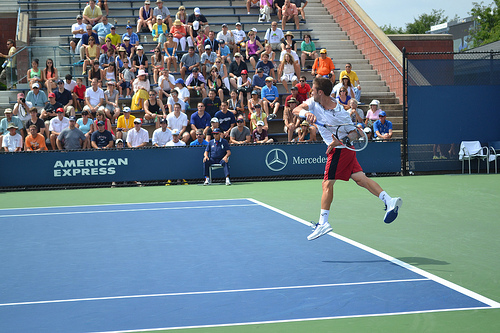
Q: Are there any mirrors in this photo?
A: No, there are no mirrors.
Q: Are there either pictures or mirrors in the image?
A: No, there are no mirrors or pictures.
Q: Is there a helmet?
A: No, there are no helmets.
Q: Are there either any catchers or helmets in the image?
A: No, there are no helmets or catchers.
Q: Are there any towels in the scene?
A: Yes, there is a towel.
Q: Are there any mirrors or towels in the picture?
A: Yes, there is a towel.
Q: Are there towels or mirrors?
A: Yes, there is a towel.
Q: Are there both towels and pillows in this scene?
A: No, there is a towel but no pillows.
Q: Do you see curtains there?
A: No, there are no curtains.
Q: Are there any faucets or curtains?
A: No, there are no curtains or faucets.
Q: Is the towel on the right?
A: Yes, the towel is on the right of the image.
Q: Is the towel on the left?
A: No, the towel is on the right of the image.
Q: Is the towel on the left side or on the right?
A: The towel is on the right of the image.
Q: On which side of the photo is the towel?
A: The towel is on the right of the image.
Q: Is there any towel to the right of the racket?
A: Yes, there is a towel to the right of the racket.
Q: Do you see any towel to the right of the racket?
A: Yes, there is a towel to the right of the racket.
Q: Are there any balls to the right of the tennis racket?
A: No, there is a towel to the right of the tennis racket.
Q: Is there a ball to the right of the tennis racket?
A: No, there is a towel to the right of the tennis racket.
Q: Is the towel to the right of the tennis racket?
A: Yes, the towel is to the right of the tennis racket.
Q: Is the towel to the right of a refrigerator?
A: No, the towel is to the right of the tennis racket.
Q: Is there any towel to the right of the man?
A: Yes, there is a towel to the right of the man.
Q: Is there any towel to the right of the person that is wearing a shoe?
A: Yes, there is a towel to the right of the man.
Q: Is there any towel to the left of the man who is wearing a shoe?
A: No, the towel is to the right of the man.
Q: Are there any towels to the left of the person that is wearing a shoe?
A: No, the towel is to the right of the man.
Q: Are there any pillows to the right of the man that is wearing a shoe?
A: No, there is a towel to the right of the man.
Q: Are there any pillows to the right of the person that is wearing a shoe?
A: No, there is a towel to the right of the man.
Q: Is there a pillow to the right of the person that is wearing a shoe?
A: No, there is a towel to the right of the man.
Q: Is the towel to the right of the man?
A: Yes, the towel is to the right of the man.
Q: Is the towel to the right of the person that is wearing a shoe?
A: Yes, the towel is to the right of the man.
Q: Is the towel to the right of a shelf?
A: No, the towel is to the right of the man.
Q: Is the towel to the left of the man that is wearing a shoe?
A: No, the towel is to the right of the man.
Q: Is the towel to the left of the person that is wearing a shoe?
A: No, the towel is to the right of the man.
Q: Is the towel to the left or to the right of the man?
A: The towel is to the right of the man.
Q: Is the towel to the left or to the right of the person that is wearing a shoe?
A: The towel is to the right of the man.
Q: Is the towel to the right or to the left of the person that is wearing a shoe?
A: The towel is to the right of the man.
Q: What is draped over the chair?
A: The towel is draped over the chair.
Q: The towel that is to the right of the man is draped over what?
A: The towel is draped over the chair.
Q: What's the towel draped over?
A: The towel is draped over the chair.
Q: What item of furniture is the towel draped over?
A: The towel is draped over the chair.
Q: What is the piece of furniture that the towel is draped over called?
A: The piece of furniture is a chair.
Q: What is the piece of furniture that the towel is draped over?
A: The piece of furniture is a chair.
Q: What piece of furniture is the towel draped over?
A: The towel is draped over the chair.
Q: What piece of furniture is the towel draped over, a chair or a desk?
A: The towel is draped over a chair.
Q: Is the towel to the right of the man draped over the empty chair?
A: Yes, the towel is draped over the chair.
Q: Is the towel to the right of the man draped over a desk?
A: No, the towel is draped over the chair.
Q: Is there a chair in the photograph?
A: Yes, there is a chair.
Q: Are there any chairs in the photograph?
A: Yes, there is a chair.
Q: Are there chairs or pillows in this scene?
A: Yes, there is a chair.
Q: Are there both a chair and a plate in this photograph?
A: No, there is a chair but no plates.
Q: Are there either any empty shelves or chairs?
A: Yes, there is an empty chair.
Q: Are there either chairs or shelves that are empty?
A: Yes, the chair is empty.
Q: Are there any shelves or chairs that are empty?
A: Yes, the chair is empty.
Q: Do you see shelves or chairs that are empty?
A: Yes, the chair is empty.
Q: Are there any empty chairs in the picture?
A: Yes, there is an empty chair.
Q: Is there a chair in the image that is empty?
A: Yes, there is a chair that is empty.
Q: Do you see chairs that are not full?
A: Yes, there is a empty chair.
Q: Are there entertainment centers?
A: No, there are no entertainment centers.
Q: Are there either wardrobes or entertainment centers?
A: No, there are no entertainment centers or wardrobes.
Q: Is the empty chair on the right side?
A: Yes, the chair is on the right of the image.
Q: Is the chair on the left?
A: No, the chair is on the right of the image.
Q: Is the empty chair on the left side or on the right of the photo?
A: The chair is on the right of the image.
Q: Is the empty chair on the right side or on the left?
A: The chair is on the right of the image.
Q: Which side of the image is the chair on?
A: The chair is on the right of the image.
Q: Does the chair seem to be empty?
A: Yes, the chair is empty.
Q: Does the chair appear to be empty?
A: Yes, the chair is empty.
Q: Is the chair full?
A: No, the chair is empty.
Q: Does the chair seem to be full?
A: No, the chair is empty.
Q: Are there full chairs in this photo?
A: No, there is a chair but it is empty.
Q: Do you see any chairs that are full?
A: No, there is a chair but it is empty.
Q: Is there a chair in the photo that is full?
A: No, there is a chair but it is empty.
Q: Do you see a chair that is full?
A: No, there is a chair but it is empty.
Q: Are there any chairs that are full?
A: No, there is a chair but it is empty.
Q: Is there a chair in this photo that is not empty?
A: No, there is a chair but it is empty.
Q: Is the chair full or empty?
A: The chair is empty.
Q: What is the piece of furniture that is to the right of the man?
A: The piece of furniture is a chair.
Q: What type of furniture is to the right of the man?
A: The piece of furniture is a chair.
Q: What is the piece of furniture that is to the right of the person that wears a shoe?
A: The piece of furniture is a chair.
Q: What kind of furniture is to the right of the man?
A: The piece of furniture is a chair.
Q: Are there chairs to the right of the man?
A: Yes, there is a chair to the right of the man.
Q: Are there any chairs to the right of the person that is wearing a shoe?
A: Yes, there is a chair to the right of the man.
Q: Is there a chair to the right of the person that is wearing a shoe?
A: Yes, there is a chair to the right of the man.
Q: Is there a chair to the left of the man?
A: No, the chair is to the right of the man.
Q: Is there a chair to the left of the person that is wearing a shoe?
A: No, the chair is to the right of the man.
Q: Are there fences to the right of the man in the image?
A: No, there is a chair to the right of the man.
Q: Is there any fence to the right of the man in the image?
A: No, there is a chair to the right of the man.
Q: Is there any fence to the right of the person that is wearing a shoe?
A: No, there is a chair to the right of the man.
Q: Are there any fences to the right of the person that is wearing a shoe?
A: No, there is a chair to the right of the man.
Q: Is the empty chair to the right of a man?
A: Yes, the chair is to the right of a man.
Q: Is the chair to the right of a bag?
A: No, the chair is to the right of a man.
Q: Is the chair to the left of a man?
A: No, the chair is to the right of a man.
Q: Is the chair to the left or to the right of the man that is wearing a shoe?
A: The chair is to the right of the man.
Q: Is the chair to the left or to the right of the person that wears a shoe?
A: The chair is to the right of the man.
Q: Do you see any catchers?
A: No, there are no catchers.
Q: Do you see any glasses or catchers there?
A: No, there are no catchers or glasses.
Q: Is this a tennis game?
A: Yes, this is a tennis game.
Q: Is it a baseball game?
A: No, this is a tennis game.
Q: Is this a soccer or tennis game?
A: This is a tennis game.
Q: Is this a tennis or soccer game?
A: This is a tennis game.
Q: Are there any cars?
A: No, there are no cars.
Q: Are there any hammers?
A: No, there are no hammers.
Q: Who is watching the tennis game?
A: The crowd is watching the game.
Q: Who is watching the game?
A: The crowd is watching the game.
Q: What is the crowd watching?
A: The crowd is watching the game.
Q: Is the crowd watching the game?
A: Yes, the crowd is watching the game.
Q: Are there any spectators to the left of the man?
A: Yes, there are spectators to the left of the man.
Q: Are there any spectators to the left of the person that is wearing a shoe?
A: Yes, there are spectators to the left of the man.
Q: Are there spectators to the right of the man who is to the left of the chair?
A: No, the spectators are to the left of the man.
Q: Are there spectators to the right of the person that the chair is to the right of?
A: No, the spectators are to the left of the man.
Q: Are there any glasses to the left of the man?
A: No, there are spectators to the left of the man.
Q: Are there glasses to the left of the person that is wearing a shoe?
A: No, there are spectators to the left of the man.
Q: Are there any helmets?
A: No, there are no helmets.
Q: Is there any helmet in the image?
A: No, there are no helmets.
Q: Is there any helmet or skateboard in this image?
A: No, there are no helmets or skateboards.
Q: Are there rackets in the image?
A: Yes, there is a racket.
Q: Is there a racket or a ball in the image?
A: Yes, there is a racket.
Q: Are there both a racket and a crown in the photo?
A: No, there is a racket but no crowns.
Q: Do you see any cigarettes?
A: No, there are no cigarettes.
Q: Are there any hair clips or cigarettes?
A: No, there are no cigarettes or hair clips.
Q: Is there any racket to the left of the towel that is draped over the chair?
A: Yes, there is a racket to the left of the towel.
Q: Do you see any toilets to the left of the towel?
A: No, there is a racket to the left of the towel.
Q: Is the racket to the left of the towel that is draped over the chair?
A: Yes, the racket is to the left of the towel.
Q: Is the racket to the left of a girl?
A: No, the racket is to the left of the towel.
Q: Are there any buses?
A: No, there are no buses.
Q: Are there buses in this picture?
A: No, there are no buses.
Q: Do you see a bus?
A: No, there are no buses.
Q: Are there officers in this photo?
A: No, there are no officers.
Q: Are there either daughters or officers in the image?
A: No, there are no officers or daughters.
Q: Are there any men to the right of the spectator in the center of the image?
A: Yes, there is a man to the right of the spectator.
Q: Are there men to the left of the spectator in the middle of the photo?
A: No, the man is to the right of the spectator.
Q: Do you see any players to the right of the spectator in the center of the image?
A: No, there is a man to the right of the spectator.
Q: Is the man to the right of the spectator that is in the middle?
A: Yes, the man is to the right of the spectator.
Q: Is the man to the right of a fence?
A: No, the man is to the right of the spectator.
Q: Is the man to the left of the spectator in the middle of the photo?
A: No, the man is to the right of the spectator.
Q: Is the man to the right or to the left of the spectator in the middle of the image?
A: The man is to the right of the spectator.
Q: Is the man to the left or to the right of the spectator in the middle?
A: The man is to the right of the spectator.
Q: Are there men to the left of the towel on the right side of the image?
A: Yes, there is a man to the left of the towel.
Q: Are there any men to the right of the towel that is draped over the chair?
A: No, the man is to the left of the towel.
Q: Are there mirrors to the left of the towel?
A: No, there is a man to the left of the towel.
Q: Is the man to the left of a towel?
A: Yes, the man is to the left of a towel.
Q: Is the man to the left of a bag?
A: No, the man is to the left of a towel.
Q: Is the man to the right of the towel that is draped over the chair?
A: No, the man is to the left of the towel.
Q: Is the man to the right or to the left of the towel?
A: The man is to the left of the towel.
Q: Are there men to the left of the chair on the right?
A: Yes, there is a man to the left of the chair.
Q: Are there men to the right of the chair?
A: No, the man is to the left of the chair.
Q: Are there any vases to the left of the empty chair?
A: No, there is a man to the left of the chair.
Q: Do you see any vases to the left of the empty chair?
A: No, there is a man to the left of the chair.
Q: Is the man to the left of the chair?
A: Yes, the man is to the left of the chair.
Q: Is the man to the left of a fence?
A: No, the man is to the left of the chair.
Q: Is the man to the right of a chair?
A: No, the man is to the left of a chair.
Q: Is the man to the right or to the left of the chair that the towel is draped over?
A: The man is to the left of the chair.